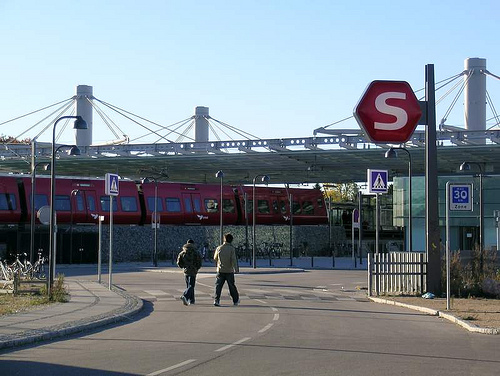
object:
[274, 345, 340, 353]
part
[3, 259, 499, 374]
road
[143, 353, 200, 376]
lines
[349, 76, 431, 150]
sign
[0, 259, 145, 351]
path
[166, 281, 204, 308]
walking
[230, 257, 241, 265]
part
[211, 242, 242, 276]
jacket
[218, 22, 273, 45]
part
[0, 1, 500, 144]
sky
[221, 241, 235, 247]
hood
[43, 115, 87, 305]
lamp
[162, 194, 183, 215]
window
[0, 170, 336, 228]
train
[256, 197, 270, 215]
window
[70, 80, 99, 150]
supports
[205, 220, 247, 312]
man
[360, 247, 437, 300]
fence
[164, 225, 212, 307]
people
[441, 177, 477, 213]
sign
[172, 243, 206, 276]
coats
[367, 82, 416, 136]
s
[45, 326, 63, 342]
boards